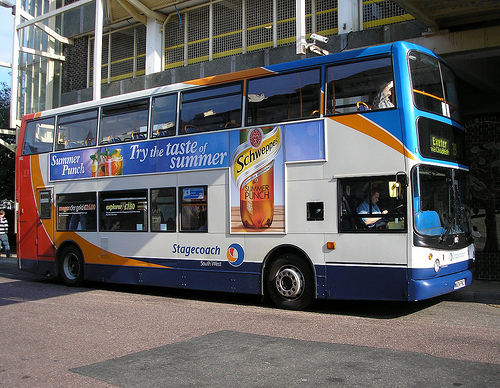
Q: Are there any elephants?
A: No, there are no elephants.